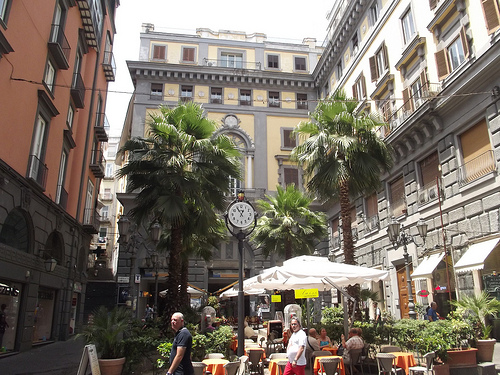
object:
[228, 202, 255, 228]
clock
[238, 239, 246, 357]
pole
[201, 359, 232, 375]
tables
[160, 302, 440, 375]
pedestrian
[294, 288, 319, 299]
sign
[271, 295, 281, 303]
sign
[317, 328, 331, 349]
woman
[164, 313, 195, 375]
man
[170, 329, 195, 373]
shirt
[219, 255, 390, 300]
umbrella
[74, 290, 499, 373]
plant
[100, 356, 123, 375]
pot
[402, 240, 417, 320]
post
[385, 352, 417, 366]
table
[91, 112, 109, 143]
balconies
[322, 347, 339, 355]
table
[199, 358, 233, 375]
orange tablecloth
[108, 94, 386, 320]
tree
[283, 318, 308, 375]
man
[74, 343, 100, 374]
sign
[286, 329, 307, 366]
shirt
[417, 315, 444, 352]
plant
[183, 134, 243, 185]
leaves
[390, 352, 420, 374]
cloth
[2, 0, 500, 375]
building